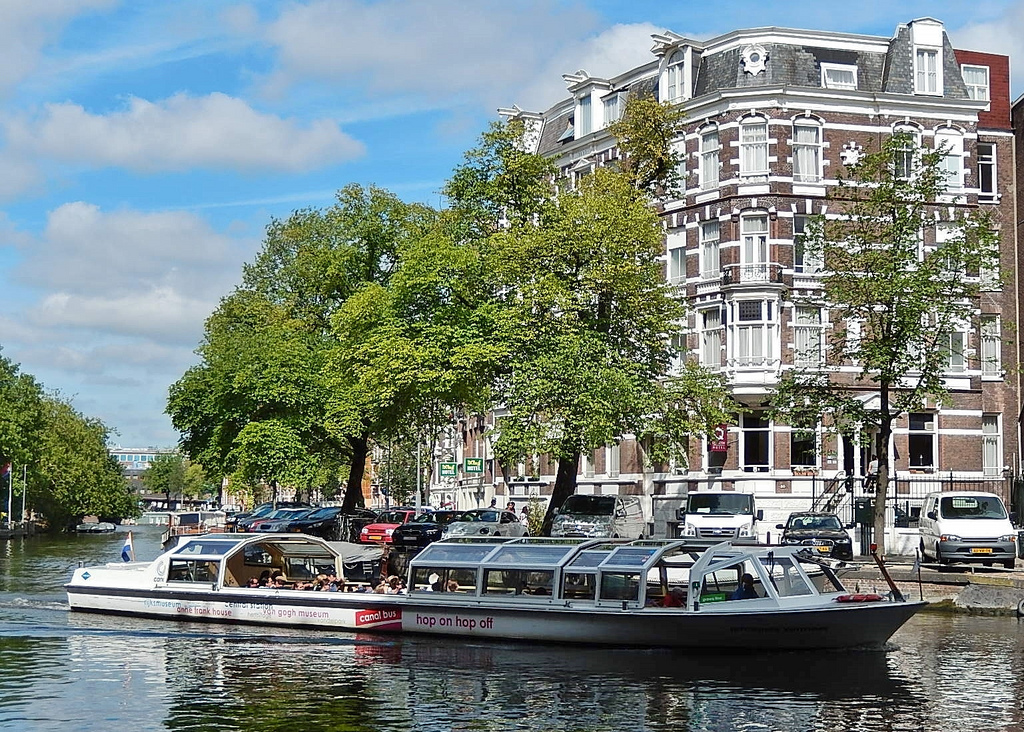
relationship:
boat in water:
[49, 467, 994, 663] [17, 514, 1014, 732]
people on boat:
[105, 453, 1003, 695] [58, 472, 970, 701]